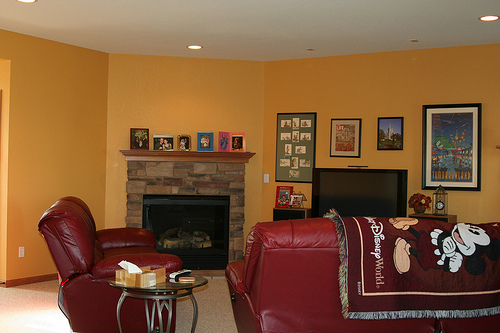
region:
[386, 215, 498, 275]
Mickey mouse on a blanket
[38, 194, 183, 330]
Dark red leather chair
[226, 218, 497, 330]
dark red leather sofa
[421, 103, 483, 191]
Picture with black frame on wall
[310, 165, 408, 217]
Black wide screen tv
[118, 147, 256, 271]
Stone fireplace mantel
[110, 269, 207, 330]
glass top metal table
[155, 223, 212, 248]
logs in a fireplace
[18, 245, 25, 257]
White colored electrical outlet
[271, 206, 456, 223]
brown and black wood speakers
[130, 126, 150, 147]
the framed picture on the mantle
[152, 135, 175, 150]
the framed picture on the mantle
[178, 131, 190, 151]
the framed picture on the mantle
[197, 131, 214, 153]
the framed picture on the mantle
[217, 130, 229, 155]
the framed picture on the mantle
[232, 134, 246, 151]
the framed picture on the mantle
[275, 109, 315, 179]
the framed picture on the wall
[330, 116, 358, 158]
the framed picture on the wall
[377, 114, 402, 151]
the framed picture on the wall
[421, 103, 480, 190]
the framed picture on the wall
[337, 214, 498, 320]
Mickey Mouse blanket over the back of the sofa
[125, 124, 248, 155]
Pictures on the fireplace mantel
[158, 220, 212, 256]
Logs in the fireplace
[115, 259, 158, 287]
Box of tissue on the table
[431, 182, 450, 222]
Anniversary clock on the table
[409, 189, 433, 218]
Flowers in a vase on the table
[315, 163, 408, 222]
Television against the wall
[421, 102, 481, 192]
Framed picture on the wall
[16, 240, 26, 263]
Electrical outlet on the wall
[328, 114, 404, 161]
Two pictures over the television set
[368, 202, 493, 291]
a mickey mouse figure on a blanket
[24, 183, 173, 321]
a large red armchair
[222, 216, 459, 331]
a large red sofa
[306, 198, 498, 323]
a disney blanket on the back of a sofa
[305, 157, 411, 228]
a flat screen TV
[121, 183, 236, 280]
a fireplace with logs in it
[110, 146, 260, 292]
a stone chimney section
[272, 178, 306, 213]
small pictures on a table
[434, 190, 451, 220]
a clock on a table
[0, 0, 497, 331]
Large room with living room furniture in it.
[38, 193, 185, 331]
Maroon chair with pillow.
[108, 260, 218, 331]
Small glass table with metal legs.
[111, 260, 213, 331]
Kleenex tissue on glass table with metal legs.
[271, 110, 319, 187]
Pictures in green and black mounted frame.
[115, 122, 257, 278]
Wood and brick fireplace.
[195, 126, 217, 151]
Photo in blue frame.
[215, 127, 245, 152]
Photo in pink double frame.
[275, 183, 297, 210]
Photo in red frame.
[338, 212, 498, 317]
Mickey Mouse throw over the sofa.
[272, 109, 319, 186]
Picture collage on the wall.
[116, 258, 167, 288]
Box of tissues on the end table.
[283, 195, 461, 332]
a blanket on the couch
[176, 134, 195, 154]
a picture on the mantel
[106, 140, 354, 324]
a fireplace made of brick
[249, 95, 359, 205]
picture on the wall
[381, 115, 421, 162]
a picture on the wall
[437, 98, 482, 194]
a picture on the wall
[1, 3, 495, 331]
Family room has carpeted floor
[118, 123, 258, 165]
Picture frames on the mantle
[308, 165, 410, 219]
Big tv screen